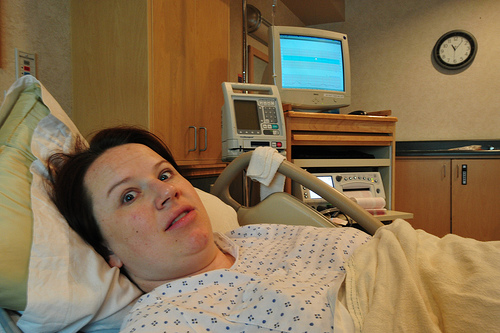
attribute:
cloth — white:
[243, 133, 281, 193]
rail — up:
[231, 7, 260, 93]